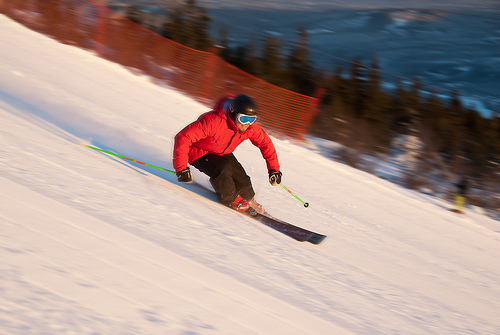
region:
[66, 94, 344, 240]
a person skiing down a mountain.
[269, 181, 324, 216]
a ski pole in man's hand.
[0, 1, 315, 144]
a safety wall on the side of a ski slope.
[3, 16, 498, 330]
a snow covered ski slope.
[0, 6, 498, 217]
a forest filled with trees.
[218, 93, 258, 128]
a person wearing snow goggles.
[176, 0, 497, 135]
a tall mountain range.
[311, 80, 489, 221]
a forest with snow.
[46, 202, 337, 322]
a section of tracks in the snow.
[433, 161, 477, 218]
a person standing in the snow.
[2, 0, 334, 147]
an orange fence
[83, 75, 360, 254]
the person is skiing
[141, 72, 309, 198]
the coat is red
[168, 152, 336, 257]
the skis are black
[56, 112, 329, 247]
the ski poles are neon colored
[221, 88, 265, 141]
the person is wearing goggles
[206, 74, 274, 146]
the person is wearing a helmet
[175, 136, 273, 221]
the pants are black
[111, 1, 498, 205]
trees behind the fence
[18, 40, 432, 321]
the snow is white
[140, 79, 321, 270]
person skiing down snowy hill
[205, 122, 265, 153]
person wearing red jacket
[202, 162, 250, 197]
person wearing black pants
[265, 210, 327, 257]
person wearing gray skis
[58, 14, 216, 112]
orange netting on ski route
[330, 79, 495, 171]
trees with green leaves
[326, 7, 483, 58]
distant mountains with trees and snow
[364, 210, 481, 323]
white snow on mountain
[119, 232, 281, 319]
white snow on mountain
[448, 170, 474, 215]
skier in stationary position on moutain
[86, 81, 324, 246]
a man skiing down a hill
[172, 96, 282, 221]
a man wearing a red coat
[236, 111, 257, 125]
a man's ski goggles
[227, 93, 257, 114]
a man's ski helmet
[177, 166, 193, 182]
a man's right hand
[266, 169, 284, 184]
a man's left hand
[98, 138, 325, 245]
a man's snow skis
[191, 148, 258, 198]
a man's black snow pants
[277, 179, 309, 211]
a man's left ski pole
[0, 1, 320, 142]
a red fence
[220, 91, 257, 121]
person wears black helmet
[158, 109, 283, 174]
person wears red jacket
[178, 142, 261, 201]
person wears dark pants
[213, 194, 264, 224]
person wears red shoes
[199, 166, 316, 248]
person wears black skis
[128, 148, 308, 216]
person holds red and green ski poles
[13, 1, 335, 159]
orange snow fence behind skier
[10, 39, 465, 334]
downhill slope is steep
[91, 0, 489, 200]
pine trees behind fence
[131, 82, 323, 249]
skier going downhill